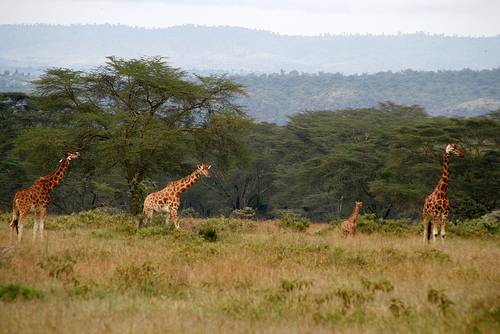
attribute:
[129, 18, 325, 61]
rise — significant 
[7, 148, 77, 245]
giraffe — in profile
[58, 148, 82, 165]
head — turned up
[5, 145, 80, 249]
giraffe — in profile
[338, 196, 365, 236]
giraffe — in distance, turned forward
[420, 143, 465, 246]
giraffe — facing forward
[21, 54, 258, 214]
tree — single, close by, large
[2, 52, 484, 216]
trees — line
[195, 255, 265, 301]
grass — light brown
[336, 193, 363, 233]
giraffe — small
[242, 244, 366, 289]
grass — brown, wavy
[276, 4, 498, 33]
sky — hazy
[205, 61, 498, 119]
mountains — gently curved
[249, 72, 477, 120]
land — sloped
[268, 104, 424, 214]
trees — feathery, green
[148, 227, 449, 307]
grasslands — tall, tan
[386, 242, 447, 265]
plants — green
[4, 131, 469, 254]
giraffes — grouped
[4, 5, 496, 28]
sky — clear, white